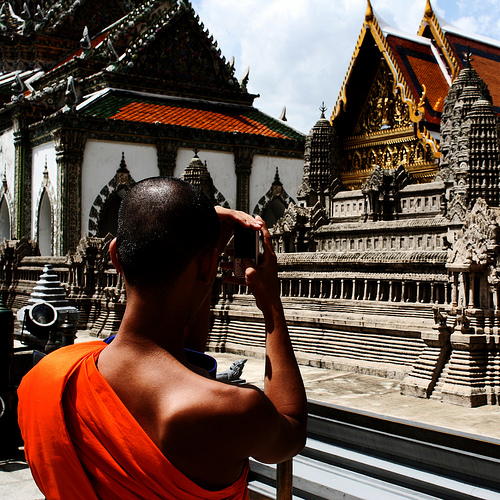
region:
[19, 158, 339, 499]
man taking a picture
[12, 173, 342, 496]
man wearing an orange toga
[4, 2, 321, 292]
white building with an orange roof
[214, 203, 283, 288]
hands holding a camera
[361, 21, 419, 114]
gold trim along the edge of the roof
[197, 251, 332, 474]
arm bent at the elbow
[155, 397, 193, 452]
bone visible in the back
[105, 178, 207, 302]
short black hair on the head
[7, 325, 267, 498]
toga only covering one shoulder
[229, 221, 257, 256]
black screen of the camera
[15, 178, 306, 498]
The man taking a picture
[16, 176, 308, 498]
The monk with orange outfit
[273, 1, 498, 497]
The temple on the right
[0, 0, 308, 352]
The temple on the left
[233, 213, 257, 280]
The gray mobile phone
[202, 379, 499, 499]
The steps to the temple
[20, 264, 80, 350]
A gray statue next to the temple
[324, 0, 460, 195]
The gold painted roof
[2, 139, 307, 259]
The white painted temple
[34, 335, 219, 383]
A blue clothing worn by a monk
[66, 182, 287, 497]
this is a man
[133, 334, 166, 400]
the man is light skinned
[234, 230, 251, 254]
this is a phone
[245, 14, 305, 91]
this is the sky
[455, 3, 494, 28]
the sky is blue in color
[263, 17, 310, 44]
these are the clouds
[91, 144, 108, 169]
this is a wall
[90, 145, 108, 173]
the wall is white in color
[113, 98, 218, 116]
this is the roof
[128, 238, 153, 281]
this is the hair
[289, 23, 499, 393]
Temple in the background.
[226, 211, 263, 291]
Cell phone in man's hands.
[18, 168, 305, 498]
Man in an orange wrap.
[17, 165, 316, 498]
Man taking photograph on phone.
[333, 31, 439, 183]
Ornate gold designs on front of building.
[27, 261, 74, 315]
Stone pillar in background.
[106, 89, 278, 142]
Orange colored roof on building.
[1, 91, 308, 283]
White building in background.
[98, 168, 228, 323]
Short black hair on man.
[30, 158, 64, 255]
Opening in the wall.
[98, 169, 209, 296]
man has short brown hair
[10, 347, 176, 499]
man wears orange tunic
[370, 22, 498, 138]
sloped orange roof on building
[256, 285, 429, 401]
grey steps in front of shrine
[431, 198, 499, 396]
sculptures are next to steps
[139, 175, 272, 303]
man has hands near eyes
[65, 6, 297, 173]
grey and red pointed roof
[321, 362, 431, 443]
light grey concrete near steps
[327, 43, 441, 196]
golden front of building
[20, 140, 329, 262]
white walls on building